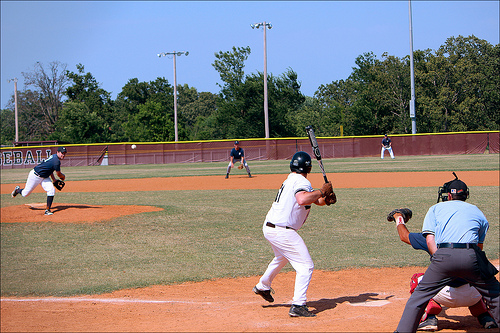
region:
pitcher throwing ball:
[9, 145, 85, 215]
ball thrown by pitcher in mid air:
[118, 137, 150, 158]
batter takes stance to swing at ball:
[256, 122, 340, 314]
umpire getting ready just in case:
[391, 159, 498, 329]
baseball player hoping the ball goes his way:
[368, 135, 408, 167]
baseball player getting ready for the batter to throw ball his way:
[223, 135, 257, 179]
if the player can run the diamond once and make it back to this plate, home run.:
[343, 287, 398, 312]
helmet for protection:
[286, 148, 317, 175]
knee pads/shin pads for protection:
[408, 270, 490, 316]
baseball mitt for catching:
[49, 175, 69, 193]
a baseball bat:
[301, 123, 338, 204]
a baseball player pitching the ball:
[13, 147, 73, 215]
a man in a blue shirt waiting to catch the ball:
[226, 142, 253, 177]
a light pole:
[154, 50, 194, 140]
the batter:
[260, 129, 338, 316]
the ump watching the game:
[412, 174, 481, 310]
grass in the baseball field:
[147, 215, 252, 271]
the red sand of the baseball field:
[1, 296, 361, 331]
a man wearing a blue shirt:
[417, 176, 499, 329]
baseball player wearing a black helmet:
[259, 138, 336, 318]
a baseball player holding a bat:
[246, 138, 353, 323]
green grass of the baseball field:
[164, 220, 229, 270]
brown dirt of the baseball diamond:
[167, 307, 229, 328]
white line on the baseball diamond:
[58, 290, 158, 309]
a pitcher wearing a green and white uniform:
[11, 130, 86, 224]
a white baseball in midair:
[126, 140, 141, 152]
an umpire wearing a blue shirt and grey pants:
[396, 183, 497, 318]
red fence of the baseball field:
[164, 145, 210, 160]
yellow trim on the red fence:
[151, 136, 218, 148]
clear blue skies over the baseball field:
[284, 8, 344, 59]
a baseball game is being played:
[8, 113, 492, 315]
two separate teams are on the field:
[24, 123, 457, 295]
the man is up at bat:
[249, 102, 336, 319]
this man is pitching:
[8, 118, 163, 232]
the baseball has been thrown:
[118, 131, 144, 155]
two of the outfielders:
[193, 112, 410, 182]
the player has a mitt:
[378, 205, 413, 222]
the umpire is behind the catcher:
[393, 177, 494, 322]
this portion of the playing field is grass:
[187, 194, 442, 254]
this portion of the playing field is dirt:
[166, 286, 438, 323]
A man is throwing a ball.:
[26, 140, 194, 192]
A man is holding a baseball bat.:
[261, 130, 333, 286]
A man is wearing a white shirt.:
[261, 172, 317, 248]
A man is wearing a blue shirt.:
[36, 145, 61, 183]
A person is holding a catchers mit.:
[371, 203, 424, 237]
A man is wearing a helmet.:
[265, 147, 315, 192]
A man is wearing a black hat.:
[436, 169, 473, 201]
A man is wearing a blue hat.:
[31, 145, 74, 156]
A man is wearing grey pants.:
[392, 245, 489, 329]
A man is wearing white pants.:
[28, 166, 56, 216]